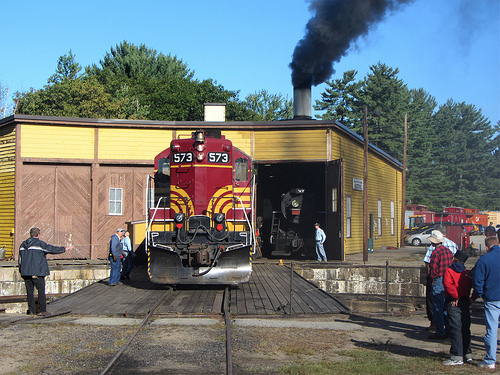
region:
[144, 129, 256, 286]
red and yellow train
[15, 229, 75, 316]
man with black and white jacket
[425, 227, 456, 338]
man wearing red plaid shirt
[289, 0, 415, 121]
black smoke coming out of a stack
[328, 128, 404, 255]
yellow building siding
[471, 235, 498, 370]
man in blue shirt and jeans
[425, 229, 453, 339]
man wearing a hat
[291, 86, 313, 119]
a silver smoke stack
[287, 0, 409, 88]
a plume of black smoke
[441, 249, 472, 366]
a young boy watching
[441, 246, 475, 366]
a young boy dressed as a train engineer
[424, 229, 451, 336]
a man standing and watching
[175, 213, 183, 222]
a train front head light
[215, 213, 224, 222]
a train front head light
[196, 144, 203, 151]
a train front head light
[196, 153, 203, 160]
a train front head light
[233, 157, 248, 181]
a train front window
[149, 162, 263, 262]
yellow trim on the train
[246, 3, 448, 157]
black smoke coming from station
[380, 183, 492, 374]
people standing next to tracks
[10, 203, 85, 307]
man has arm extended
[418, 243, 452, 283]
person wearing plaid shirt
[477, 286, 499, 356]
man wearing blue jeans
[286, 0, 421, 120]
black smoke coming out of stack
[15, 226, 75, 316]
man wearing black jacket with white stripe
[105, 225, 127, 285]
conductor wearing blue clothing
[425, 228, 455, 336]
man wearing a red plaid shirt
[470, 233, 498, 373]
man wearing blue jeans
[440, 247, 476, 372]
person wearing red shirt with blue hood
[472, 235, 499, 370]
man wearing a blue sweatshirt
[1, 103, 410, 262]
yellow building with wood panels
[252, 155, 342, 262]
black train inside of building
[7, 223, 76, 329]
This is a person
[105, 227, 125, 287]
This is a person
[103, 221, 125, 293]
This is a person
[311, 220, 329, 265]
This is a person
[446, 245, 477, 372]
This is a person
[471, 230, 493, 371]
This is a person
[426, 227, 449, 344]
This is a person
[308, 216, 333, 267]
This is a person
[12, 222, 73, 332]
This is a person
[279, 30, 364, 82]
The black smoke coming from the building.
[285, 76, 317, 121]
The gray smoke stack emitting smoke.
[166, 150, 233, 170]
The numbers that are on the red train.